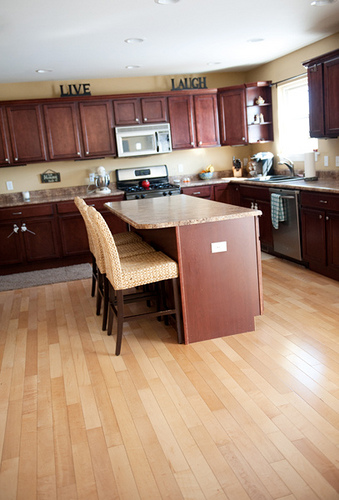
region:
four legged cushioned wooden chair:
[68, 198, 185, 354]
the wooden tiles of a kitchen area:
[1, 363, 332, 498]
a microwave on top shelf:
[109, 117, 181, 157]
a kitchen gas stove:
[110, 164, 184, 195]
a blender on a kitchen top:
[90, 161, 114, 194]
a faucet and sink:
[247, 156, 303, 185]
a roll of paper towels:
[298, 144, 321, 182]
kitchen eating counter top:
[102, 196, 265, 344]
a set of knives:
[227, 155, 245, 177]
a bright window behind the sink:
[265, 66, 321, 164]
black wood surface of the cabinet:
[195, 268, 242, 312]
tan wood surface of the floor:
[144, 404, 292, 477]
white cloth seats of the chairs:
[97, 234, 150, 282]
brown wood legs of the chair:
[101, 294, 146, 352]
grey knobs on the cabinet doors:
[308, 209, 335, 224]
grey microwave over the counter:
[111, 126, 173, 160]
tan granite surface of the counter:
[149, 206, 190, 220]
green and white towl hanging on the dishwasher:
[263, 190, 290, 230]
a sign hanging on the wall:
[32, 165, 69, 185]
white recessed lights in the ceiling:
[116, 23, 152, 76]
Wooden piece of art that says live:
[55, 80, 93, 100]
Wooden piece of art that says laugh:
[168, 74, 208, 92]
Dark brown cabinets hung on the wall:
[0, 46, 338, 169]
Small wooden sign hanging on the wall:
[36, 168, 62, 185]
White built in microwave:
[111, 120, 173, 159]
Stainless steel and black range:
[113, 163, 183, 200]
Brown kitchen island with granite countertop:
[102, 191, 265, 346]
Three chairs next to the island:
[66, 193, 185, 357]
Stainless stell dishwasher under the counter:
[265, 182, 305, 263]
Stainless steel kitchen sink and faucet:
[240, 154, 306, 184]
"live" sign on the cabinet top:
[58, 81, 90, 98]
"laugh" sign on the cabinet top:
[170, 76, 210, 90]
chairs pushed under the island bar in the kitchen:
[70, 196, 182, 357]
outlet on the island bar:
[206, 240, 228, 253]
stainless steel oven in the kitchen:
[114, 160, 181, 201]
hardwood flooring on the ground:
[0, 254, 337, 498]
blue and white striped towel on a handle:
[267, 190, 289, 229]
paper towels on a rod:
[301, 151, 319, 183]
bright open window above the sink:
[275, 77, 318, 163]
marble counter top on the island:
[101, 195, 266, 230]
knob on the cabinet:
[195, 140, 209, 151]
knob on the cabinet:
[188, 142, 197, 148]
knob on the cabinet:
[239, 135, 246, 142]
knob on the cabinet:
[313, 213, 322, 222]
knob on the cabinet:
[322, 215, 329, 222]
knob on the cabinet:
[84, 151, 92, 158]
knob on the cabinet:
[73, 150, 81, 155]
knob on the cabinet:
[12, 158, 19, 164]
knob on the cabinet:
[4, 158, 8, 164]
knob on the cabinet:
[21, 223, 29, 236]